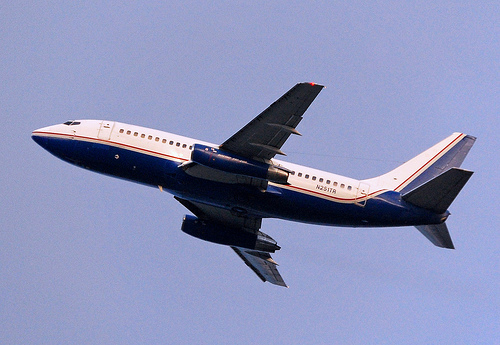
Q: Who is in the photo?
A: No one.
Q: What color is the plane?
A: White and blue.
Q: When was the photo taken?
A: Daytime.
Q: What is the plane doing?
A: Flying.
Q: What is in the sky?
A: Plane.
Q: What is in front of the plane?
A: Nothing.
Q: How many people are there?
A: None.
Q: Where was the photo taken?
A: In the sky.